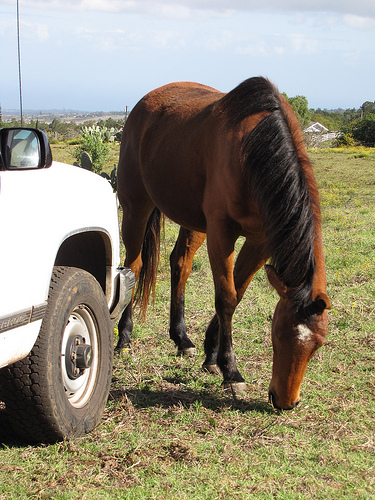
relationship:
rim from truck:
[62, 302, 99, 410] [3, 127, 138, 443]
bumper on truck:
[113, 262, 136, 326] [3, 127, 138, 443]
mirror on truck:
[2, 125, 52, 168] [3, 127, 138, 443]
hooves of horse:
[225, 378, 244, 394] [115, 73, 332, 413]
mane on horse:
[243, 102, 319, 314] [115, 73, 332, 413]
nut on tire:
[70, 351, 79, 361] [18, 267, 114, 438]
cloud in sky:
[0, 0, 375, 64] [1, 0, 373, 115]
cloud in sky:
[39, 23, 181, 65] [1, 0, 373, 115]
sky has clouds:
[82, 7, 313, 82] [164, 4, 279, 59]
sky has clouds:
[0, 0, 375, 118] [173, 7, 242, 58]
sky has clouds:
[0, 0, 375, 118] [69, 22, 143, 76]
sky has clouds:
[0, 0, 375, 118] [39, 21, 128, 68]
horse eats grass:
[115, 73, 332, 413] [243, 413, 350, 452]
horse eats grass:
[115, 73, 332, 413] [248, 411, 354, 462]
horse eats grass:
[88, 68, 335, 428] [253, 407, 355, 452]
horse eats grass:
[88, 68, 335, 428] [239, 413, 373, 458]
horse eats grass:
[115, 73, 332, 413] [230, 408, 369, 467]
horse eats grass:
[115, 73, 332, 413] [235, 414, 367, 459]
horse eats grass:
[115, 73, 332, 413] [223, 406, 353, 461]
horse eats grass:
[115, 73, 332, 413] [243, 412, 343, 460]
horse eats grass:
[115, 73, 332, 413] [222, 413, 331, 458]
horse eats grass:
[115, 73, 332, 413] [255, 410, 342, 458]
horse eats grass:
[88, 68, 335, 428] [224, 409, 371, 447]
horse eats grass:
[115, 73, 332, 413] [239, 410, 320, 464]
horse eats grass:
[115, 73, 332, 413] [236, 417, 349, 474]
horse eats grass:
[88, 68, 335, 428] [243, 417, 341, 466]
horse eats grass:
[115, 73, 332, 413] [236, 404, 368, 467]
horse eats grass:
[115, 73, 332, 413] [241, 408, 347, 476]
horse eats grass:
[115, 73, 332, 413] [243, 398, 364, 442]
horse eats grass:
[115, 73, 332, 413] [241, 418, 373, 471]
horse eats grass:
[115, 73, 332, 413] [248, 406, 346, 474]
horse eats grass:
[88, 68, 335, 428] [249, 412, 350, 482]